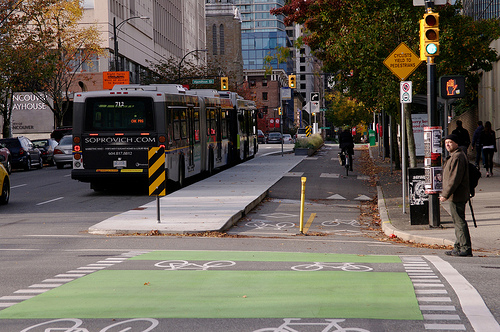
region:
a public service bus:
[68, 84, 201, 196]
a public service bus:
[195, 89, 227, 166]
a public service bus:
[227, 93, 262, 159]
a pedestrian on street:
[432, 132, 481, 252]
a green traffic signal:
[412, 9, 442, 229]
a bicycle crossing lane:
[107, 254, 399, 273]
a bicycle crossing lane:
[5, 313, 419, 329]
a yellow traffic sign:
[377, 40, 421, 80]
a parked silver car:
[49, 133, 77, 165]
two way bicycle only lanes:
[238, 141, 374, 231]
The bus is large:
[73, 82, 256, 190]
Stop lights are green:
[219, 8, 440, 92]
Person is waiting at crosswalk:
[440, 135, 477, 257]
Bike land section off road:
[1, 141, 469, 328]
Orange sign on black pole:
[103, 71, 129, 91]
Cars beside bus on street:
[0, 134, 79, 211]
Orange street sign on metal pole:
[381, 42, 421, 216]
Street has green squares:
[4, 247, 422, 320]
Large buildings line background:
[1, 2, 498, 141]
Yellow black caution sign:
[144, 146, 169, 233]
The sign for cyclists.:
[376, 36, 422, 79]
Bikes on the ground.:
[153, 254, 383, 281]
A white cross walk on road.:
[395, 251, 498, 330]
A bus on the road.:
[69, 70, 261, 193]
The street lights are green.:
[217, 73, 299, 90]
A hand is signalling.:
[440, 77, 462, 98]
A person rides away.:
[334, 123, 360, 182]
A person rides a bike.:
[331, 123, 359, 175]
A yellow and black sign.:
[142, 143, 172, 226]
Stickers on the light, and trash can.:
[406, 125, 444, 230]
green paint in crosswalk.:
[182, 282, 330, 294]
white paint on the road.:
[419, 258, 449, 320]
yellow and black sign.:
[151, 150, 164, 191]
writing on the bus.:
[82, 134, 152, 143]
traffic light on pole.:
[424, 17, 437, 62]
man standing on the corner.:
[440, 147, 477, 252]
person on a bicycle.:
[330, 114, 356, 184]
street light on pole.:
[111, 13, 154, 29]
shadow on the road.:
[40, 177, 66, 199]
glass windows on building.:
[251, 32, 266, 57]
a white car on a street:
[55, 83, 265, 180]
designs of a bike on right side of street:
[143, 253, 375, 283]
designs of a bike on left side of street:
[13, 309, 380, 329]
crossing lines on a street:
[402, 245, 497, 327]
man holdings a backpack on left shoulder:
[432, 126, 485, 261]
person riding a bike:
[330, 115, 358, 181]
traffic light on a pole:
[410, 5, 445, 67]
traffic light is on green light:
[410, 5, 445, 65]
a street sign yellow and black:
[135, 137, 172, 223]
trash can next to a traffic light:
[398, 160, 443, 227]